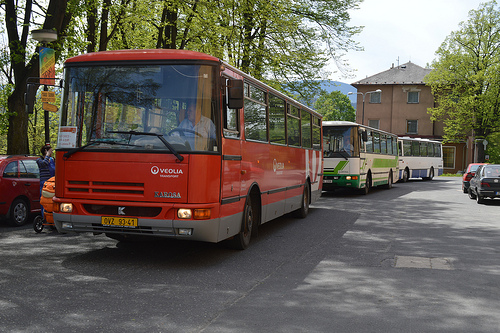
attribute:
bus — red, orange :
[47, 53, 321, 252]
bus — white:
[395, 136, 445, 182]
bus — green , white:
[318, 120, 403, 193]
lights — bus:
[53, 192, 193, 224]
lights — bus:
[47, 195, 197, 227]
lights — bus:
[55, 189, 205, 226]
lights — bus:
[48, 188, 202, 228]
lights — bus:
[45, 196, 207, 231]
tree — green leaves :
[213, 16, 223, 30]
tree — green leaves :
[200, 7, 220, 30]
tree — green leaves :
[448, 50, 479, 95]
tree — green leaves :
[441, 52, 484, 99]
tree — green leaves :
[454, 50, 484, 116]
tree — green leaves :
[125, 12, 263, 32]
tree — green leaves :
[324, 97, 334, 107]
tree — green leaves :
[456, 46, 472, 118]